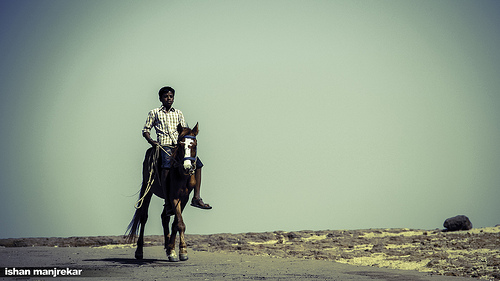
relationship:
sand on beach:
[340, 228, 447, 258] [0, 227, 499, 280]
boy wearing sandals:
[140, 85, 212, 210] [189, 195, 209, 209]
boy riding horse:
[142, 86, 212, 209] [124, 121, 204, 265]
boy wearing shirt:
[140, 85, 212, 210] [139, 108, 187, 148]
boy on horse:
[140, 85, 212, 210] [120, 120, 200, 264]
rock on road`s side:
[439, 212, 473, 231] [6, 221, 497, 279]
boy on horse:
[140, 85, 212, 210] [115, 141, 199, 225]